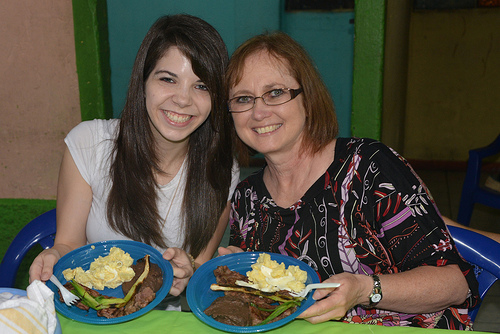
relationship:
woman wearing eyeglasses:
[227, 60, 408, 269] [228, 89, 308, 112]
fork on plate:
[291, 282, 332, 296] [186, 267, 206, 295]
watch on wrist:
[371, 276, 384, 303] [384, 270, 399, 304]